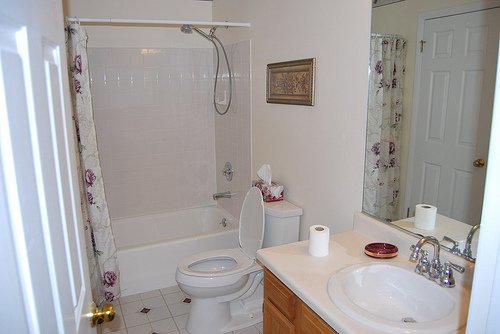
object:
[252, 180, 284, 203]
box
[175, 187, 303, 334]
commode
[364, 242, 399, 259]
soap dish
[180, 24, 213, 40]
shower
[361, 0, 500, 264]
mirror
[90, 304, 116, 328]
handle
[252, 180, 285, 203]
tissue box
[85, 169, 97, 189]
flower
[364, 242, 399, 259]
dish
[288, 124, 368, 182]
wall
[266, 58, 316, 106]
frame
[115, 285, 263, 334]
floor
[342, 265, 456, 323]
sink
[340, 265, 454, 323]
bowl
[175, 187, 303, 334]
toilet bowl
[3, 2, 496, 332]
room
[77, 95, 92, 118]
white flower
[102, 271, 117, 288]
purple roses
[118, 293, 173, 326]
floor tile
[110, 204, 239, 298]
bathtub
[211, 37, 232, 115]
hose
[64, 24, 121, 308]
shower curtain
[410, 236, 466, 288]
faucet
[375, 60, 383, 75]
flower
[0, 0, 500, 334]
toilet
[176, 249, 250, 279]
seat down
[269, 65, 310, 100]
framed picture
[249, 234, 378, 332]
vanity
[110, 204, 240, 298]
white tub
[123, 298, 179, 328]
linoleum floor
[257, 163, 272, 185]
paper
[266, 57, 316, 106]
decor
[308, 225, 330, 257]
paper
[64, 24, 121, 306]
curtain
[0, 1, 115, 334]
door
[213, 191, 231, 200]
faucet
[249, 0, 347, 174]
wall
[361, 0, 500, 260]
reflection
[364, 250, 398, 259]
stripe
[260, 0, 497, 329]
vanity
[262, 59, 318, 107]
picture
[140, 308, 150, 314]
diamonds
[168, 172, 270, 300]
seat up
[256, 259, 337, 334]
cabinet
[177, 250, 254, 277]
sits